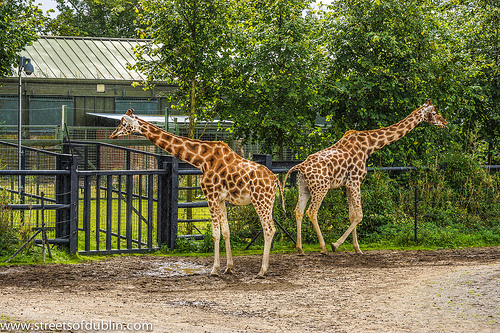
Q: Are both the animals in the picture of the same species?
A: Yes, all the animals are giraffes.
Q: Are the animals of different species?
A: No, all the animals are giraffes.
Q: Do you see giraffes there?
A: Yes, there is a giraffe.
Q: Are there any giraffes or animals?
A: Yes, there is a giraffe.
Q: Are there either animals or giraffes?
A: Yes, there is a giraffe.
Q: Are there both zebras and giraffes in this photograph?
A: No, there is a giraffe but no zebras.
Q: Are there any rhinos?
A: No, there are no rhinos.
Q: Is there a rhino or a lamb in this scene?
A: No, there are no rhinos or lambs.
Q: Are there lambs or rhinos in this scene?
A: No, there are no rhinos or lambs.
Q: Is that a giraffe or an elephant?
A: That is a giraffe.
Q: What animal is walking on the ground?
A: The giraffe is walking on the ground.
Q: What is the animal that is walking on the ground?
A: The animal is a giraffe.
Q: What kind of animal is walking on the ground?
A: The animal is a giraffe.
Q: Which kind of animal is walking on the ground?
A: The animal is a giraffe.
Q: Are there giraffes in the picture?
A: Yes, there is a giraffe.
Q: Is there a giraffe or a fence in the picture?
A: Yes, there is a giraffe.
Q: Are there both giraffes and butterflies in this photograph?
A: No, there is a giraffe but no butterflies.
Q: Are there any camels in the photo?
A: No, there are no camels.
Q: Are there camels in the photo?
A: No, there are no camels.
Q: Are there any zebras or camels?
A: No, there are no camels or zebras.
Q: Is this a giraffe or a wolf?
A: This is a giraffe.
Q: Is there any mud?
A: Yes, there is mud.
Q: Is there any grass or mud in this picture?
A: Yes, there is mud.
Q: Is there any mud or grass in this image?
A: Yes, there is mud.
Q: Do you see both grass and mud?
A: Yes, there are both mud and grass.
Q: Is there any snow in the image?
A: No, there is no snow.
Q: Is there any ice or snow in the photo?
A: No, there are no snow or ice.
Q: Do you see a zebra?
A: No, there are no zebras.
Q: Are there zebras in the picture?
A: No, there are no zebras.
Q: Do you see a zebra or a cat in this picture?
A: No, there are no zebras or cats.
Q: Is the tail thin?
A: Yes, the tail is thin.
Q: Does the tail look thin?
A: Yes, the tail is thin.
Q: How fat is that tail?
A: The tail is thin.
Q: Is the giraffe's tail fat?
A: No, the tail is thin.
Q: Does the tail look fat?
A: No, the tail is thin.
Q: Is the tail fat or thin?
A: The tail is thin.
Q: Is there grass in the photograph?
A: Yes, there is grass.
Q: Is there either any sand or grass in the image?
A: Yes, there is grass.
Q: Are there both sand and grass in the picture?
A: Yes, there are both grass and sand.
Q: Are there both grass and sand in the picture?
A: Yes, there are both grass and sand.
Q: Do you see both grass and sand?
A: Yes, there are both grass and sand.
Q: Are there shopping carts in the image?
A: No, there are no shopping carts.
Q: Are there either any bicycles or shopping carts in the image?
A: No, there are no shopping carts or bicycles.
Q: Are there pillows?
A: No, there are no pillows.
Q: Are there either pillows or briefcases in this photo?
A: No, there are no pillows or briefcases.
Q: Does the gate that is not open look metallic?
A: Yes, the gate is metallic.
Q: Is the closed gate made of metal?
A: Yes, the gate is made of metal.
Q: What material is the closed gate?
A: The gate is made of metal.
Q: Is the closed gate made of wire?
A: No, the gate is made of metal.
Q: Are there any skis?
A: No, there are no skis.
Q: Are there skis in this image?
A: No, there are no skis.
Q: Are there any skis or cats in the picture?
A: No, there are no skis or cats.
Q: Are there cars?
A: No, there are no cars.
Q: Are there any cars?
A: No, there are no cars.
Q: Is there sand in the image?
A: Yes, there is sand.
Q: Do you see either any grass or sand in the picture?
A: Yes, there is sand.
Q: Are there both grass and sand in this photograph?
A: Yes, there are both sand and grass.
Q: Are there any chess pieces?
A: No, there are no chess pieces.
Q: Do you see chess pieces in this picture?
A: No, there are no chess pieces.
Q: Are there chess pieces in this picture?
A: No, there are no chess pieces.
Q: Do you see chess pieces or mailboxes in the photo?
A: No, there are no chess pieces or mailboxes.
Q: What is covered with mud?
A: The ground is covered with mud.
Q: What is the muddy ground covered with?
A: The ground is covered with mud.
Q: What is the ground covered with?
A: The ground is covered with mud.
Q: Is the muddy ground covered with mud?
A: Yes, the ground is covered with mud.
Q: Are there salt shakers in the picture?
A: No, there are no salt shakers.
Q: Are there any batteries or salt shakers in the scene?
A: No, there are no salt shakers or batteries.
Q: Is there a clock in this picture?
A: No, there are no clocks.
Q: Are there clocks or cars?
A: No, there are no clocks or cars.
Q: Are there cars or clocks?
A: No, there are no clocks or cars.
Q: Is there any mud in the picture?
A: Yes, there is mud.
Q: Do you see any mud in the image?
A: Yes, there is mud.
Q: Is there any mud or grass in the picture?
A: Yes, there is mud.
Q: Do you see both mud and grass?
A: Yes, there are both mud and grass.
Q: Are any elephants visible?
A: No, there are no elephants.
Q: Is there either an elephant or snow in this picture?
A: No, there are no elephants or snow.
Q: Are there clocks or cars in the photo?
A: No, there are no cars or clocks.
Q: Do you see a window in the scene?
A: Yes, there is a window.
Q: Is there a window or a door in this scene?
A: Yes, there is a window.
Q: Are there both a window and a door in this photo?
A: No, there is a window but no doors.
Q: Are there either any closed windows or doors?
A: Yes, there is a closed window.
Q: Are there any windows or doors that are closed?
A: Yes, the window is closed.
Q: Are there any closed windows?
A: Yes, there is a closed window.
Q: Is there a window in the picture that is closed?
A: Yes, there is a window that is closed.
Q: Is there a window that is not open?
A: Yes, there is an closed window.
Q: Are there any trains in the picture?
A: No, there are no trains.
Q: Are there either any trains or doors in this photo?
A: No, there are no trains or doors.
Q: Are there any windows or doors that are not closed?
A: No, there is a window but it is closed.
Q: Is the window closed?
A: Yes, the window is closed.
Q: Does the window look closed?
A: Yes, the window is closed.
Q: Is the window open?
A: No, the window is closed.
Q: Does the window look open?
A: No, the window is closed.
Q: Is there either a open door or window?
A: No, there is a window but it is closed.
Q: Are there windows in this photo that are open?
A: No, there is a window but it is closed.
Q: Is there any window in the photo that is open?
A: No, there is a window but it is closed.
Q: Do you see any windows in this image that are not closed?
A: No, there is a window but it is closed.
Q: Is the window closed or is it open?
A: The window is closed.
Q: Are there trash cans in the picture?
A: No, there are no trash cans.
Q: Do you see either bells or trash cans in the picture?
A: No, there are no trash cans or bells.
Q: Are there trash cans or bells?
A: No, there are no trash cans or bells.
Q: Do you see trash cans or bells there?
A: No, there are no trash cans or bells.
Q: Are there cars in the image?
A: No, there are no cars.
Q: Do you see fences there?
A: Yes, there is a fence.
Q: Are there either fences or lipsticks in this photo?
A: Yes, there is a fence.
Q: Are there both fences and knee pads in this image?
A: No, there is a fence but no knee pads.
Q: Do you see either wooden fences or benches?
A: Yes, there is a wood fence.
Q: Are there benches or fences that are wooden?
A: Yes, the fence is wooden.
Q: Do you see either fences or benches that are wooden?
A: Yes, the fence is wooden.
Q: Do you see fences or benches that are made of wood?
A: Yes, the fence is made of wood.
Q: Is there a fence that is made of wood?
A: Yes, there is a fence that is made of wood.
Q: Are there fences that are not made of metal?
A: Yes, there is a fence that is made of wood.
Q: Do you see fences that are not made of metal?
A: Yes, there is a fence that is made of wood.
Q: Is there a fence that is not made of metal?
A: Yes, there is a fence that is made of wood.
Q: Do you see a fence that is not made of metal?
A: Yes, there is a fence that is made of wood.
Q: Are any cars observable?
A: No, there are no cars.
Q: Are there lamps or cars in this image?
A: No, there are no cars or lamps.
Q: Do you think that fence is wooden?
A: Yes, the fence is wooden.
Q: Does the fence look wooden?
A: Yes, the fence is wooden.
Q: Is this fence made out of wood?
A: Yes, the fence is made of wood.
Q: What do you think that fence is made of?
A: The fence is made of wood.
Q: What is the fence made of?
A: The fence is made of wood.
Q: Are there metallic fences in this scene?
A: No, there is a fence but it is wooden.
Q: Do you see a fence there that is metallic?
A: No, there is a fence but it is wooden.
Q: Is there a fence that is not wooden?
A: No, there is a fence but it is wooden.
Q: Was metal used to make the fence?
A: No, the fence is made of wood.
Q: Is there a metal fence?
A: No, there is a fence but it is made of wood.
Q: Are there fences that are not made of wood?
A: No, there is a fence but it is made of wood.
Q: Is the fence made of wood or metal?
A: The fence is made of wood.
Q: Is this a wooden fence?
A: Yes, this is a wooden fence.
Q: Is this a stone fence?
A: No, this is a wooden fence.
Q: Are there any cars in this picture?
A: No, there are no cars.